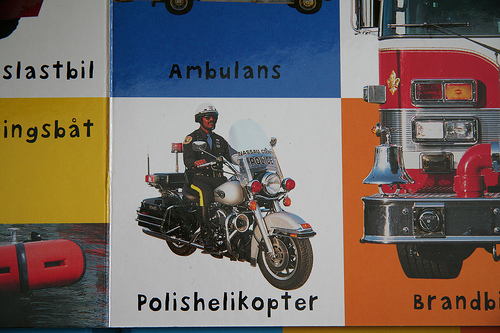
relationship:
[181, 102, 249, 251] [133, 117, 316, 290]
police riding motorcycle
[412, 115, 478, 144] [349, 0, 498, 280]
headlights on front of fire truck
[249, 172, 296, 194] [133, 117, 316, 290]
headlights on front of motorcycle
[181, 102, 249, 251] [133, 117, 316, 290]
police on top of motorcycle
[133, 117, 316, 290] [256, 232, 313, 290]
motorcycle has front wheel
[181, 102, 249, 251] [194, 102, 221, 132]
police has head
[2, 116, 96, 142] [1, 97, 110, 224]
writing printed on square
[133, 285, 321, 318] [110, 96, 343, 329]
writing printed on square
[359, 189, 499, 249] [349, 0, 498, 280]
bumper on front of fire truck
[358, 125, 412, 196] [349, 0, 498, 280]
bell on side of fire truck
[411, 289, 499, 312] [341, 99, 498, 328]
writing printed on square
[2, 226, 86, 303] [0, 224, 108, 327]
sea tube over water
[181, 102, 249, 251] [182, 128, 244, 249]
police wearing uniform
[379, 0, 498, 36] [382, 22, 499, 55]
window has window wiper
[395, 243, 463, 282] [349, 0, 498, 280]
tire on bottom of fire truck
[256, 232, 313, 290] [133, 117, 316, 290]
front wheel of motorcycle